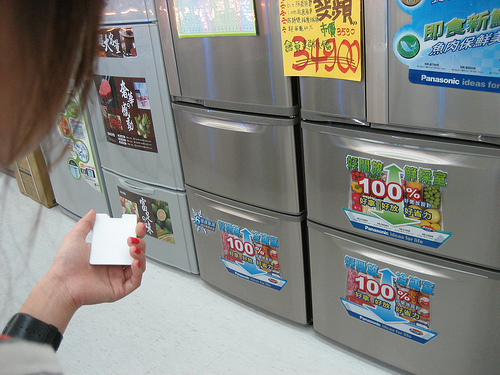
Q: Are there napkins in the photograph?
A: No, there are no napkins.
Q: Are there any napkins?
A: No, there are no napkins.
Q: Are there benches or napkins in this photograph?
A: No, there are no napkins or benches.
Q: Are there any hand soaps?
A: No, there are no hand soaps.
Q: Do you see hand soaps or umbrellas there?
A: No, there are no hand soaps or umbrellas.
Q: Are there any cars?
A: No, there are no cars.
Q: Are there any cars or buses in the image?
A: No, there are no cars or buses.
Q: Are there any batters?
A: No, there are no batters.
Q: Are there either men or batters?
A: No, there are no batters or men.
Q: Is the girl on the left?
A: Yes, the girl is on the left of the image.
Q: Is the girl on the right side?
A: No, the girl is on the left of the image.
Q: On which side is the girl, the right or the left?
A: The girl is on the left of the image.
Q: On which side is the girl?
A: The girl is on the left of the image.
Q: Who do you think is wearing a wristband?
A: The girl is wearing a wristband.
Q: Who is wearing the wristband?
A: The girl is wearing a wristband.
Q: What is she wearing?
A: The girl is wearing a wrist band.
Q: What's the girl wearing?
A: The girl is wearing a wrist band.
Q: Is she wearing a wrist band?
A: Yes, the girl is wearing a wrist band.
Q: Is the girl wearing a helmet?
A: No, the girl is wearing a wrist band.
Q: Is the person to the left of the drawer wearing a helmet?
A: No, the girl is wearing a wrist band.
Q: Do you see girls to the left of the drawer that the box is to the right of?
A: Yes, there is a girl to the left of the drawer.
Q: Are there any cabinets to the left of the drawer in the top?
A: No, there is a girl to the left of the drawer.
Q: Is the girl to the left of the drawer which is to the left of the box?
A: Yes, the girl is to the left of the drawer.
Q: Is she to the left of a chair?
A: No, the girl is to the left of the drawer.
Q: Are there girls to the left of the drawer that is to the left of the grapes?
A: Yes, there is a girl to the left of the drawer.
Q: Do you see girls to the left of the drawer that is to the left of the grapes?
A: Yes, there is a girl to the left of the drawer.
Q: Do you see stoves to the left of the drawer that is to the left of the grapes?
A: No, there is a girl to the left of the drawer.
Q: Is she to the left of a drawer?
A: Yes, the girl is to the left of a drawer.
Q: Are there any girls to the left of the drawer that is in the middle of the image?
A: Yes, there is a girl to the left of the drawer.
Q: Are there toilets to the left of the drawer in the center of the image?
A: No, there is a girl to the left of the drawer.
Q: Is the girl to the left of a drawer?
A: Yes, the girl is to the left of a drawer.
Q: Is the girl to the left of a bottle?
A: No, the girl is to the left of a drawer.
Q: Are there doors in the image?
A: Yes, there is a door.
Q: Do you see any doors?
A: Yes, there is a door.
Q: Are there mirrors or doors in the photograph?
A: Yes, there is a door.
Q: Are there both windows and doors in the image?
A: No, there is a door but no windows.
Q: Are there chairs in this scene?
A: No, there are no chairs.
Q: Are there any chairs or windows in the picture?
A: No, there are no chairs or windows.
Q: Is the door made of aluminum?
A: Yes, the door is made of aluminum.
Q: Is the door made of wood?
A: No, the door is made of aluminum.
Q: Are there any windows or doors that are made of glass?
A: No, there is a door but it is made of aluminum.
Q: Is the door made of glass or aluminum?
A: The door is made of aluminum.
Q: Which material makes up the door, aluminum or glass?
A: The door is made of aluminum.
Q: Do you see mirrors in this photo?
A: No, there are no mirrors.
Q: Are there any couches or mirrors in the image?
A: No, there are no mirrors or couches.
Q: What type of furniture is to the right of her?
A: The piece of furniture is a drawer.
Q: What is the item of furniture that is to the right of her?
A: The piece of furniture is a drawer.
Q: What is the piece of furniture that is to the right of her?
A: The piece of furniture is a drawer.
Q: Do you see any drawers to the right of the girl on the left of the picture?
A: Yes, there is a drawer to the right of the girl.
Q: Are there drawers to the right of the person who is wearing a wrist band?
A: Yes, there is a drawer to the right of the girl.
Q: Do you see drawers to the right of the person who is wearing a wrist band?
A: Yes, there is a drawer to the right of the girl.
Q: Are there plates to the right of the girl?
A: No, there is a drawer to the right of the girl.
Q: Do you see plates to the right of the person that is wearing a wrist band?
A: No, there is a drawer to the right of the girl.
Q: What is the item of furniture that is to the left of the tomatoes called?
A: The piece of furniture is a drawer.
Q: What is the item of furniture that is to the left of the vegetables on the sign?
A: The piece of furniture is a drawer.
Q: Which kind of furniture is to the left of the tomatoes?
A: The piece of furniture is a drawer.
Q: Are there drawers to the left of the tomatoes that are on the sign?
A: Yes, there is a drawer to the left of the tomatoes.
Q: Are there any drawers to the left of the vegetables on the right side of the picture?
A: Yes, there is a drawer to the left of the tomatoes.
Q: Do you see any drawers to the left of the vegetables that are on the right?
A: Yes, there is a drawer to the left of the tomatoes.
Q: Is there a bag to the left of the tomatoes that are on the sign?
A: No, there is a drawer to the left of the tomatoes.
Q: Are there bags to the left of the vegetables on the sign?
A: No, there is a drawer to the left of the tomatoes.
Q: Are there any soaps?
A: No, there are no soaps.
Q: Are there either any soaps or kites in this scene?
A: No, there are no soaps or kites.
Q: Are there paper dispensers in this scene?
A: No, there are no paper dispensers.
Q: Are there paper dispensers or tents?
A: No, there are no paper dispensers or tents.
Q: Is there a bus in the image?
A: No, there are no buses.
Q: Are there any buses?
A: No, there are no buses.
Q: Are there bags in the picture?
A: No, there are no bags.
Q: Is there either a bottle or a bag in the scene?
A: No, there are no bags or bottles.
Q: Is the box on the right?
A: Yes, the box is on the right of the image.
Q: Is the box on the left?
A: No, the box is on the right of the image.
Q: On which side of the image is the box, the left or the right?
A: The box is on the right of the image.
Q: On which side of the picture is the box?
A: The box is on the right of the image.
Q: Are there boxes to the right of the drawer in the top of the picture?
A: Yes, there is a box to the right of the drawer.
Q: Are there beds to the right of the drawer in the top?
A: No, there is a box to the right of the drawer.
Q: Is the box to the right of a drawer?
A: Yes, the box is to the right of a drawer.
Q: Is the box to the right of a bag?
A: No, the box is to the right of a drawer.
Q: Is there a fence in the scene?
A: No, there are no fences.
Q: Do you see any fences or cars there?
A: No, there are no fences or cars.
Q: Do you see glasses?
A: No, there are no glasses.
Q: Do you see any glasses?
A: No, there are no glasses.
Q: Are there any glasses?
A: No, there are no glasses.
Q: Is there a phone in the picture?
A: Yes, there is a phone.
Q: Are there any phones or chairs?
A: Yes, there is a phone.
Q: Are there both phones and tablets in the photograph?
A: No, there is a phone but no tablets.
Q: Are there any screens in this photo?
A: No, there are no screens.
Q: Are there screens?
A: No, there are no screens.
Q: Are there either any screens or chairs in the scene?
A: No, there are no screens or chairs.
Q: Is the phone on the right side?
A: No, the phone is on the left of the image.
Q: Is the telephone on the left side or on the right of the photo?
A: The telephone is on the left of the image.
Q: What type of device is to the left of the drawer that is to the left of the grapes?
A: The device is a phone.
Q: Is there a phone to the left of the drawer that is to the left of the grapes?
A: Yes, there is a phone to the left of the drawer.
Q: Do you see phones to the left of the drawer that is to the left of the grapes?
A: Yes, there is a phone to the left of the drawer.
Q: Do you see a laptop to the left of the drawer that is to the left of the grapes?
A: No, there is a phone to the left of the drawer.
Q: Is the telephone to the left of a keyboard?
A: No, the telephone is to the left of the drawer.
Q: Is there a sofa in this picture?
A: No, there are no sofas.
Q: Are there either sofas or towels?
A: No, there are no sofas or towels.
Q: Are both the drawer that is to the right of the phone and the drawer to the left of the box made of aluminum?
A: Yes, both the drawer and the drawer are made of aluminum.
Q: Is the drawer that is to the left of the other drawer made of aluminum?
A: Yes, the drawer is made of aluminum.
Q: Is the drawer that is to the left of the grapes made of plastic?
A: No, the drawer is made of aluminum.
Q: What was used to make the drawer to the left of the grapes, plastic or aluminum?
A: The drawer is made of aluminum.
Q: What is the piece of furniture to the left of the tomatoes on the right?
A: The piece of furniture is a drawer.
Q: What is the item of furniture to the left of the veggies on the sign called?
A: The piece of furniture is a drawer.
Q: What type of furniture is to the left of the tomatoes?
A: The piece of furniture is a drawer.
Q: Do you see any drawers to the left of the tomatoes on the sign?
A: Yes, there is a drawer to the left of the tomatoes.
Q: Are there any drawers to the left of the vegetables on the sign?
A: Yes, there is a drawer to the left of the tomatoes.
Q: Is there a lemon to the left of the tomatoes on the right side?
A: No, there is a drawer to the left of the tomatoes.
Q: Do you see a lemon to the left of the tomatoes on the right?
A: No, there is a drawer to the left of the tomatoes.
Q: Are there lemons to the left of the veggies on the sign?
A: No, there is a drawer to the left of the tomatoes.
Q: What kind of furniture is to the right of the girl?
A: The piece of furniture is a drawer.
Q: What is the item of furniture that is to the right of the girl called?
A: The piece of furniture is a drawer.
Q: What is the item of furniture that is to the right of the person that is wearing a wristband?
A: The piece of furniture is a drawer.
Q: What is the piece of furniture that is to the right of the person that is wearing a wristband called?
A: The piece of furniture is a drawer.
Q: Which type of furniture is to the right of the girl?
A: The piece of furniture is a drawer.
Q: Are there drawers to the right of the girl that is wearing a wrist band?
A: Yes, there is a drawer to the right of the girl.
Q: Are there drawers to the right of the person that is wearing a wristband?
A: Yes, there is a drawer to the right of the girl.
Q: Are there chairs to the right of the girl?
A: No, there is a drawer to the right of the girl.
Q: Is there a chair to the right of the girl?
A: No, there is a drawer to the right of the girl.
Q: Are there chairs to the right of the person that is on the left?
A: No, there is a drawer to the right of the girl.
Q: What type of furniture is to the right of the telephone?
A: The piece of furniture is a drawer.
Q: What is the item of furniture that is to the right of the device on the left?
A: The piece of furniture is a drawer.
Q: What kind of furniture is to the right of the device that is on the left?
A: The piece of furniture is a drawer.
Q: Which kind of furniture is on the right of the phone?
A: The piece of furniture is a drawer.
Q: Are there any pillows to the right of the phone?
A: No, there is a drawer to the right of the phone.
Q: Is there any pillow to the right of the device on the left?
A: No, there is a drawer to the right of the phone.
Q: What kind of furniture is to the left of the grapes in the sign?
A: The piece of furniture is a drawer.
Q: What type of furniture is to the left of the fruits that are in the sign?
A: The piece of furniture is a drawer.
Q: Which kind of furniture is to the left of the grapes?
A: The piece of furniture is a drawer.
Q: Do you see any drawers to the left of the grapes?
A: Yes, there is a drawer to the left of the grapes.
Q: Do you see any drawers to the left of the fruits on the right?
A: Yes, there is a drawer to the left of the grapes.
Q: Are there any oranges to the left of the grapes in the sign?
A: No, there is a drawer to the left of the grapes.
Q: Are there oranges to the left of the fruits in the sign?
A: No, there is a drawer to the left of the grapes.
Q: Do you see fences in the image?
A: No, there are no fences.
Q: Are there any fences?
A: No, there are no fences.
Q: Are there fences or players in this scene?
A: No, there are no fences or players.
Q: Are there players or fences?
A: No, there are no fences or players.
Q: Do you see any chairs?
A: No, there are no chairs.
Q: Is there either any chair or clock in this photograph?
A: No, there are no chairs or clocks.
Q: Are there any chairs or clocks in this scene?
A: No, there are no chairs or clocks.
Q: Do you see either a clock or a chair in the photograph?
A: No, there are no chairs or clocks.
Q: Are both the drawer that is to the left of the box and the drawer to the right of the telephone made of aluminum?
A: Yes, both the drawer and the drawer are made of aluminum.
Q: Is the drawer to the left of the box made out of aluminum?
A: Yes, the drawer is made of aluminum.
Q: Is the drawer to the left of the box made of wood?
A: No, the drawer is made of aluminum.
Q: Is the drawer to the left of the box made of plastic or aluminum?
A: The drawer is made of aluminum.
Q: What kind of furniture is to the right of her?
A: The piece of furniture is a drawer.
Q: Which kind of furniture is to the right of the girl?
A: The piece of furniture is a drawer.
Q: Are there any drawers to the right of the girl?
A: Yes, there is a drawer to the right of the girl.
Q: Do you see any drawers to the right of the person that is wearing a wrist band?
A: Yes, there is a drawer to the right of the girl.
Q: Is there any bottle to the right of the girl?
A: No, there is a drawer to the right of the girl.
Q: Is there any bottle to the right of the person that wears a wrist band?
A: No, there is a drawer to the right of the girl.